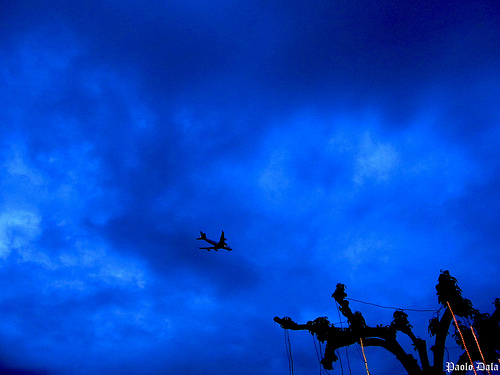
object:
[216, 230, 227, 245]
wing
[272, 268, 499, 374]
tree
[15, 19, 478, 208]
air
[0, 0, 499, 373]
clouds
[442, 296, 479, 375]
lights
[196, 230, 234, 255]
plane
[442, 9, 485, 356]
right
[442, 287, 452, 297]
leaves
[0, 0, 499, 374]
sky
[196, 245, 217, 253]
wing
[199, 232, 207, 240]
tail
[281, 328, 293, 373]
string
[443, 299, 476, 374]
string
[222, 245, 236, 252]
nose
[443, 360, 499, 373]
watermark